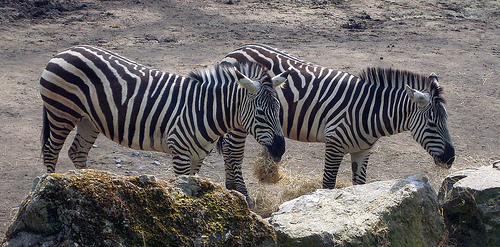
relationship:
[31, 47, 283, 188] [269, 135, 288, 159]
zebra has nose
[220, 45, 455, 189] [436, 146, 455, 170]
zebra has nose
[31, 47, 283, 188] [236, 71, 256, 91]
zebra has ear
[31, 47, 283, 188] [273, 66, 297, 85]
zebra has ear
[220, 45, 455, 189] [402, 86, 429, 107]
zebra has ear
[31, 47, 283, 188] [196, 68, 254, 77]
zebra has mane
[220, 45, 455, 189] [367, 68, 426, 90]
zebra has mane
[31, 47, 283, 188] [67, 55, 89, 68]
zebra has stripe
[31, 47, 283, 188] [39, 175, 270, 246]
zebra next to rock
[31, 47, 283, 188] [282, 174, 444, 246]
zebra next to rock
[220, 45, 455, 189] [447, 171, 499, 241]
zebra next to rock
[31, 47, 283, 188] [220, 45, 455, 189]
zebra next to zebra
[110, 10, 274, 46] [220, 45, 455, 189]
dirt behind zebra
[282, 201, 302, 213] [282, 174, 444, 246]
sunlight shining on rock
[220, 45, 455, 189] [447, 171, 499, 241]
zebra looking at rock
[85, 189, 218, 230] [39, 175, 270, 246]
moss covering rock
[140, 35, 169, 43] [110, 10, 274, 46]
track on top of dirt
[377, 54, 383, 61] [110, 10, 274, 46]
pebble on top of dirt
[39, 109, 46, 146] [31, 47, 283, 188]
hair handing from zebra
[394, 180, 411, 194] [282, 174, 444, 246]
shadow cast upon rock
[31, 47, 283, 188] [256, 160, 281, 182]
zebra eating hay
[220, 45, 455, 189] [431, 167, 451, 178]
zebra eating hay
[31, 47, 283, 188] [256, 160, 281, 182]
zebra chewing on hay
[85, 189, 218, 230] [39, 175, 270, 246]
moss growing on rock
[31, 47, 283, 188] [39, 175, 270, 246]
zebra standing by rock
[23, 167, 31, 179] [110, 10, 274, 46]
pebble lying on dirt